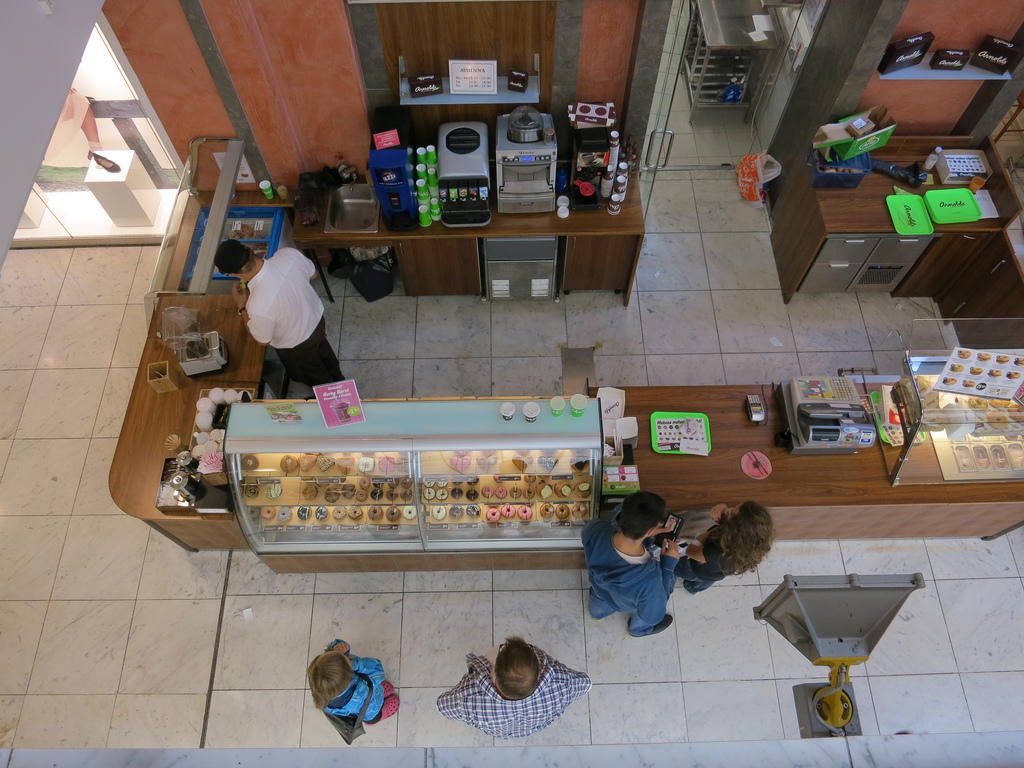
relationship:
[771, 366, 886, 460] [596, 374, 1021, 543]
cash register on counter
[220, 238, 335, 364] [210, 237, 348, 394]
shirt on man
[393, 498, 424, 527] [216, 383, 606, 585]
doughnut in display counter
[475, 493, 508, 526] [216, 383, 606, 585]
doughnut in display counter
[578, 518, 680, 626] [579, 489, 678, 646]
sweater on man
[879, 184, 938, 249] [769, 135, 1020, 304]
tray on desk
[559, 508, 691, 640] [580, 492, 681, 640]
sweater on man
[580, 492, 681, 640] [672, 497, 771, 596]
man next to lady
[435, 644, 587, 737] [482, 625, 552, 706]
man has head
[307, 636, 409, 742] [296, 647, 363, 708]
woman has head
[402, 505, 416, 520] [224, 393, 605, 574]
doughnut in display counter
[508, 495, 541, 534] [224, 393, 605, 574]
donut in display counter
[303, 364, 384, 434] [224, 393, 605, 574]
sign on top of display counter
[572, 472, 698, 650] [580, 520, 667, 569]
man has neck